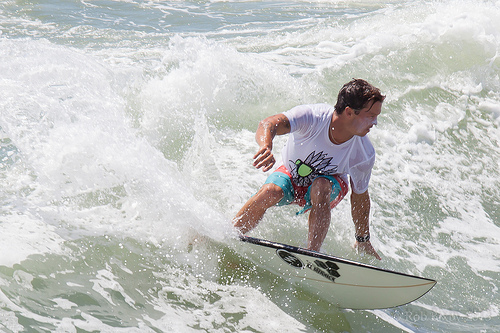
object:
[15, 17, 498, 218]
wave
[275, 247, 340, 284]
design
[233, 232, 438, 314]
board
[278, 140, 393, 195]
lake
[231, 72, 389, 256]
man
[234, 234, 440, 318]
shorts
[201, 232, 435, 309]
surfboard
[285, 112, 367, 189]
shirt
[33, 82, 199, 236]
splash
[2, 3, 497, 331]
water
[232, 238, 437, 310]
white surfboard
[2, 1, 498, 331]
ocean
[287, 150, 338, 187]
design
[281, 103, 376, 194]
t-shirt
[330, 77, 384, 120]
hair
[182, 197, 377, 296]
line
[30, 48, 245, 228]
froth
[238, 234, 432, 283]
details